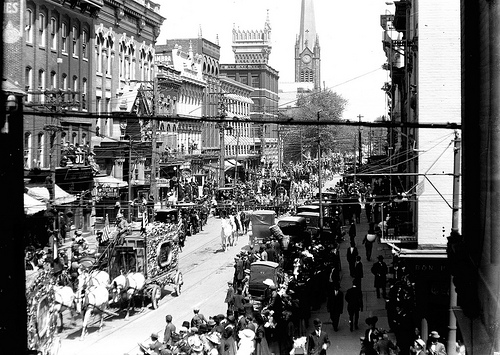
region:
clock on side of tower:
[297, 49, 312, 64]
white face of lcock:
[303, 55, 308, 64]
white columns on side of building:
[88, 47, 148, 75]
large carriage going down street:
[98, 215, 183, 278]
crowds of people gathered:
[154, 250, 344, 353]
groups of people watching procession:
[164, 244, 339, 353]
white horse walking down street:
[213, 216, 235, 245]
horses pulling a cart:
[18, 197, 191, 329]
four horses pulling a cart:
[39, 261, 151, 331]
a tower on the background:
[288, 0, 330, 96]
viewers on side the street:
[144, 275, 298, 348]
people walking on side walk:
[317, 210, 384, 353]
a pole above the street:
[25, 94, 454, 144]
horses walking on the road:
[206, 204, 248, 251]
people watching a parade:
[151, 142, 341, 312]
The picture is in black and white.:
[6, 2, 498, 352]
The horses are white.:
[71, 265, 146, 330]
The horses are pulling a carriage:
[70, 265, 144, 341]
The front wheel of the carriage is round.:
[150, 287, 164, 307]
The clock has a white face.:
[298, 50, 311, 65]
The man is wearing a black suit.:
[329, 282, 344, 329]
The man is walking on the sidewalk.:
[325, 282, 343, 332]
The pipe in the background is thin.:
[348, 170, 458, 178]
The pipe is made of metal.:
[342, 168, 458, 178]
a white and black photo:
[1, 4, 496, 354]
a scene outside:
[3, 4, 498, 349]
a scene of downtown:
[3, 0, 498, 353]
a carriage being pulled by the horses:
[8, 198, 190, 350]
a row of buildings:
[0, 0, 332, 254]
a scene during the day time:
[5, 4, 497, 353]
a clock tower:
[280, 0, 335, 111]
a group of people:
[205, 147, 460, 354]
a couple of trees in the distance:
[274, 75, 421, 164]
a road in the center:
[19, 160, 464, 350]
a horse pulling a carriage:
[103, 266, 158, 322]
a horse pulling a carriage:
[73, 285, 112, 339]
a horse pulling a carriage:
[30, 283, 79, 333]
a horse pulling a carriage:
[70, 267, 112, 308]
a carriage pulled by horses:
[100, 217, 190, 307]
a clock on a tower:
[300, 50, 312, 62]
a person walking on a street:
[340, 278, 365, 329]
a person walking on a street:
[323, 280, 344, 333]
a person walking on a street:
[341, 241, 359, 276]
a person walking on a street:
[300, 318, 332, 353]